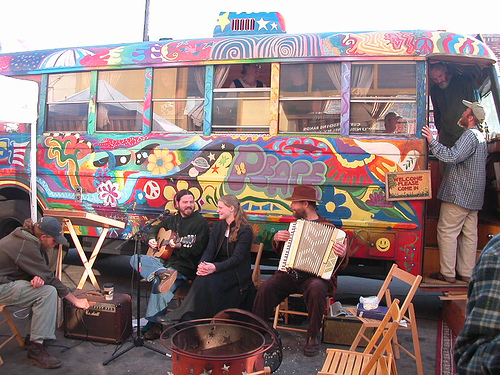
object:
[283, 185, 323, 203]
hat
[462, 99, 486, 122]
hat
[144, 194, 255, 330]
person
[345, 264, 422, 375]
chair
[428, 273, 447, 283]
boot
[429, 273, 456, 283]
foot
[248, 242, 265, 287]
chair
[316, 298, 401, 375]
chair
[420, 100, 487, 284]
man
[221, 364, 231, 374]
star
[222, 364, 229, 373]
hole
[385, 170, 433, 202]
sign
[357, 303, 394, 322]
book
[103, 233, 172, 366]
microphone stand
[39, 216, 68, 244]
cap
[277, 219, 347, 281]
accordian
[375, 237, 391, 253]
sticker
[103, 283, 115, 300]
cup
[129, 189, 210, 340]
man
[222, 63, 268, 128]
woman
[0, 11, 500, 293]
bus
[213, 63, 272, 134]
open window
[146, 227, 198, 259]
guitar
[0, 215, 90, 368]
man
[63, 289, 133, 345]
amp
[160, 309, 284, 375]
fire pit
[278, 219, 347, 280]
instrument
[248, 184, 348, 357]
man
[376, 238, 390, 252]
smiley face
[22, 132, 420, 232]
designs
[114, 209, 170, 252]
microphone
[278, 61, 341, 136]
window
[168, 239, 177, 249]
hand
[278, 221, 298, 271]
keys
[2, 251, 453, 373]
ground